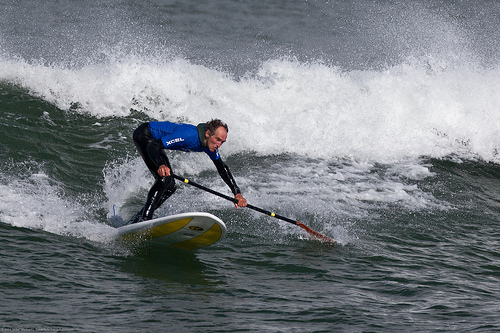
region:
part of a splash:
[298, 112, 338, 152]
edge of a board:
[190, 206, 215, 245]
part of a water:
[305, 203, 322, 235]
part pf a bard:
[190, 211, 207, 238]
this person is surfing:
[56, 81, 383, 288]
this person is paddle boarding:
[84, 89, 390, 280]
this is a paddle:
[160, 155, 365, 252]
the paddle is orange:
[287, 213, 345, 254]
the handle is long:
[150, 160, 337, 230]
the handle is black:
[149, 157, 326, 234]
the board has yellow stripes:
[99, 182, 281, 264]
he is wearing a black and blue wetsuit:
[97, 77, 262, 262]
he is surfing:
[52, 86, 382, 301]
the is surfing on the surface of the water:
[80, 65, 395, 279]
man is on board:
[115, 132, 215, 232]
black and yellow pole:
[175, 171, 345, 253]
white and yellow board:
[107, 210, 241, 271]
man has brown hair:
[202, 124, 230, 144]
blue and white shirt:
[162, 93, 201, 148]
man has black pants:
[138, 130, 183, 215]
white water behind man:
[242, 144, 395, 224]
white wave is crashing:
[70, 73, 492, 165]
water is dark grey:
[318, 218, 468, 331]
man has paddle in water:
[112, 114, 343, 263]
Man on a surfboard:
[95, 108, 251, 251]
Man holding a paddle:
[128, 103, 349, 234]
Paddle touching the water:
[171, 175, 368, 237]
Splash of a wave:
[86, 51, 473, 142]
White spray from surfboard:
[94, 144, 162, 226]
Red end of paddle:
[295, 215, 341, 247]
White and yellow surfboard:
[103, 214, 245, 246]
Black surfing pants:
[133, 125, 174, 222]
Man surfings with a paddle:
[86, 100, 246, 259]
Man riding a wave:
[91, 113, 249, 250]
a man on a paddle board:
[95, 91, 307, 303]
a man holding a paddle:
[138, 108, 330, 294]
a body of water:
[244, 121, 459, 331]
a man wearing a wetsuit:
[51, 89, 300, 284]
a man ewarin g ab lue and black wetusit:
[84, 69, 259, 238]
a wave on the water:
[208, 80, 493, 222]